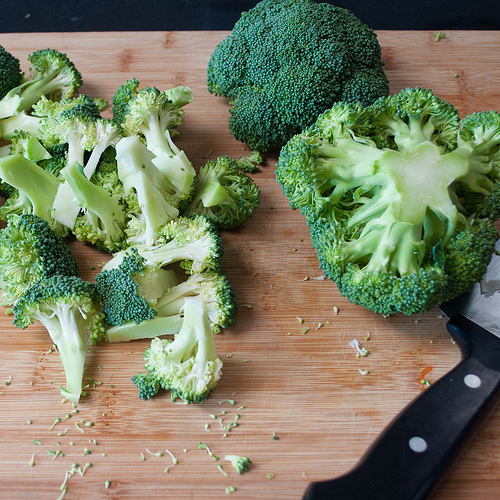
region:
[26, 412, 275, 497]
piceces of broccoli on the board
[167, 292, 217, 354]
The stock of the broccoli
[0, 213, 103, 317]
the bushy green broccoli head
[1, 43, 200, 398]
Cut up pieces of broccoli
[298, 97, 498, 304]
A head of broccoli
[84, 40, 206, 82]
A wooden cutting board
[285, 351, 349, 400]
Lines in the wood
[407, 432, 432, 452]
A circle on the handle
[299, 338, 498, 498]
The handle of the knife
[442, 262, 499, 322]
The knife blade with broccoli on it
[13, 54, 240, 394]
The chopped up pieces of broccoli.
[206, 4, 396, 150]
The bunch of broccoli showing the top of the vegetable.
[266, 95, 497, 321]
The bunch of broccoli turned upside down.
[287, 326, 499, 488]
The black handle of the knife.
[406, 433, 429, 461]
The bottom gray dot on the handle of the knife.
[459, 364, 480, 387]
The top gray dot on the handle of the knife.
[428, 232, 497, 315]
The blade of the knife.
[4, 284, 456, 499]
The tiny pieces of broccoli on the cutting board.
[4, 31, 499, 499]
The wooden cutting board the broccoli and knife are placed on.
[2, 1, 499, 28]
The black table the cutting board and broccoli is placed on.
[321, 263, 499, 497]
knife with black handle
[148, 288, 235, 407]
chopped fresh broccoli stem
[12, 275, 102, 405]
chopped fresh broccoli stem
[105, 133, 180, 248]
chopped fresh broccoli stem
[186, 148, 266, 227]
chopped fresh broccoli stem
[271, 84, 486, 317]
chopped fresh broccoli stem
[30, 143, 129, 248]
chopped fresh broccoli stem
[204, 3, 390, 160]
chopped fresh broccoli stem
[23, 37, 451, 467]
broccoli on wooden cutting board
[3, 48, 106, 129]
chopped fresh broccoli stem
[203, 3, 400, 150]
a large green broccoli floret.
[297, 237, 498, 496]
a knife with a black handle.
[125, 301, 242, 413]
a section of green broccoli.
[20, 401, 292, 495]
broccoli debris on a wooden table.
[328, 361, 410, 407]
a wet spot.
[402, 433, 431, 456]
a bolt holding a knife handle.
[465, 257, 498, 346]
a knife blade.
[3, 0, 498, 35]
the edge of a cutting board.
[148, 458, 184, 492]
a small broccoli debris.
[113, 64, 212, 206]
a piece of broccoli.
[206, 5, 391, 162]
dark green broccoli on cutting board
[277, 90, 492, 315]
head of broccoli on cutting board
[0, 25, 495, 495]
wooden cutting board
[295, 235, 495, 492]
black and silver knife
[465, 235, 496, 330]
shiny silver knife blade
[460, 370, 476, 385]
silver rivet in knife handle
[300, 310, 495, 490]
black handle on knife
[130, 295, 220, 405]
light green cut broccoli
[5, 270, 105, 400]
dark and light green cut broccoli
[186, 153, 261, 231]
cut broccoli near broccoli head